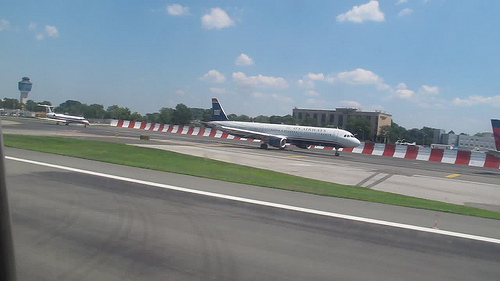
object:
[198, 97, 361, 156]
plane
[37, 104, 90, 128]
plane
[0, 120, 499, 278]
runway